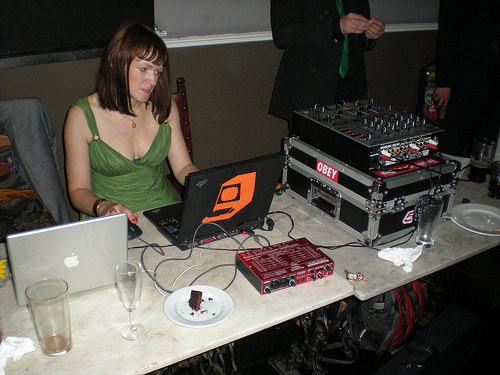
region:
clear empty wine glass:
[116, 260, 151, 338]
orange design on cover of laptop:
[216, 173, 291, 232]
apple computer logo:
[54, 235, 91, 285]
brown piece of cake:
[173, 277, 235, 344]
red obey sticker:
[308, 157, 355, 195]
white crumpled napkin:
[366, 237, 433, 280]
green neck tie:
[334, 1, 364, 86]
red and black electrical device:
[231, 242, 361, 298]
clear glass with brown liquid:
[468, 132, 498, 195]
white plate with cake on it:
[168, 281, 238, 333]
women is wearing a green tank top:
[98, 152, 168, 198]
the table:
[86, 312, 121, 352]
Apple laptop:
[23, 231, 110, 268]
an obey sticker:
[313, 158, 346, 183]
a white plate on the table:
[175, 296, 187, 318]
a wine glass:
[110, 271, 149, 311]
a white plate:
[465, 202, 487, 234]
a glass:
[422, 198, 442, 244]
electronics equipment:
[311, 101, 428, 159]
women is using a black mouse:
[123, 213, 148, 238]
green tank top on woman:
[48, 96, 181, 220]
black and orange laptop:
[184, 154, 288, 270]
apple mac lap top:
[17, 217, 145, 301]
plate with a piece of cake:
[164, 284, 272, 349]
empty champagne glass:
[109, 270, 165, 338]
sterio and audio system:
[301, 92, 417, 222]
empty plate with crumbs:
[444, 203, 498, 231]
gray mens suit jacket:
[1, 91, 85, 216]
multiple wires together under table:
[332, 302, 484, 358]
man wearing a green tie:
[303, 3, 388, 113]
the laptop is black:
[124, 110, 389, 358]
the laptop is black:
[149, 164, 327, 341]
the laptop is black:
[136, 131, 284, 289]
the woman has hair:
[96, 77, 121, 107]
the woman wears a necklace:
[113, 111, 148, 138]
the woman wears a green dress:
[81, 125, 165, 172]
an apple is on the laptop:
[61, 249, 86, 271]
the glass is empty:
[96, 257, 153, 345]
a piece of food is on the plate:
[159, 279, 236, 331]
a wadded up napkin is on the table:
[380, 237, 422, 277]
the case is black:
[284, 136, 409, 245]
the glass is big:
[14, 272, 76, 358]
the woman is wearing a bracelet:
[56, 19, 208, 208]